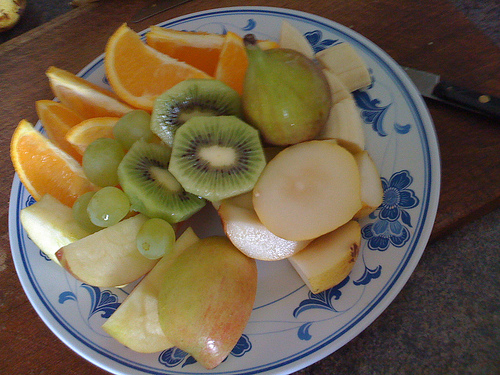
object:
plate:
[358, 66, 439, 278]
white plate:
[37, 17, 412, 352]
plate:
[351, 260, 384, 285]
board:
[390, 13, 497, 209]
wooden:
[388, 3, 485, 64]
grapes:
[66, 105, 179, 262]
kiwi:
[167, 114, 267, 199]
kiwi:
[147, 77, 243, 145]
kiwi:
[119, 138, 204, 221]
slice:
[270, 154, 372, 245]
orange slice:
[41, 62, 134, 118]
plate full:
[75, 54, 360, 341]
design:
[352, 73, 414, 147]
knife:
[398, 54, 498, 145]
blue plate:
[386, 175, 433, 254]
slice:
[209, 30, 253, 108]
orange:
[98, 20, 211, 100]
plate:
[3, 3, 448, 373]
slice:
[110, 37, 182, 87]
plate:
[375, 112, 430, 181]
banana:
[259, 31, 389, 138]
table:
[369, 41, 491, 232]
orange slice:
[63, 115, 159, 152]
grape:
[79, 135, 126, 187]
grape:
[110, 108, 154, 149]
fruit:
[10, 23, 378, 375]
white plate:
[336, 41, 448, 262]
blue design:
[375, 168, 412, 242]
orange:
[22, 88, 102, 159]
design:
[329, 159, 423, 295]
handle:
[430, 74, 484, 117]